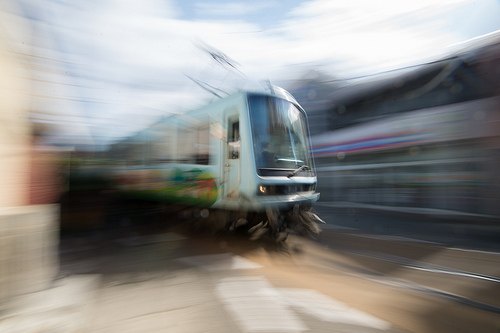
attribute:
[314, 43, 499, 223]
bullet train — red striped, blue striped, speeding, out of focus, silver, extremely fast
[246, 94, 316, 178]
train — blurry, blue, very fast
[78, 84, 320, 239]
train — speeding, blue, edged, moving, colorful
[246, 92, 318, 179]
windshield — very large, large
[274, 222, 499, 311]
tracks — partial, edged, gravelled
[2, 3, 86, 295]
train depot — blurred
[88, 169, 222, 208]
logo — colorful, green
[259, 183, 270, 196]
headlight — partial, on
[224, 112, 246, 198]
door — partial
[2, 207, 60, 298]
wall — concrete, short, stone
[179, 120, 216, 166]
window — partial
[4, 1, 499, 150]
sky — blue, cloudy